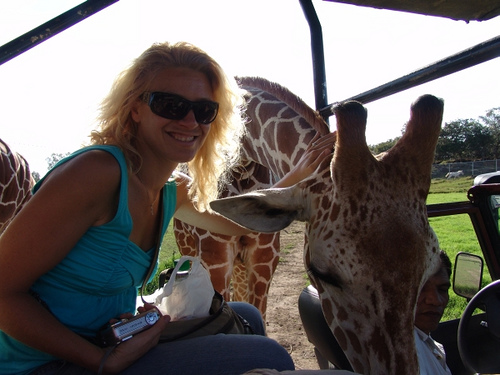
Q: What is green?
A: Grass.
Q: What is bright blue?
A: Woman's shirt.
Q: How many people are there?
A: One.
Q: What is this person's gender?
A: Female.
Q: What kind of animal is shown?
A: Giraffe.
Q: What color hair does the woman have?
A: Blond.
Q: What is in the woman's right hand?
A: A camera.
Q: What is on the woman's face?
A: Sunglasses.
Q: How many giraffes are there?
A: Two.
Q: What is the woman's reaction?
A: Smiling.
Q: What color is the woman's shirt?
A: Teal.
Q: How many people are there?
A: Two.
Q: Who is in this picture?
A: A woman.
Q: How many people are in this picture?
A: One.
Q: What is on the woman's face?
A: Sunglasses.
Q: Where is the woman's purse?
A: Lap.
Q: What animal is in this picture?
A: Giraffe.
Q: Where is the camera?
A: In the woman's hand.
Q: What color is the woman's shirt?
A: Blue.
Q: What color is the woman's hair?
A: Blonde.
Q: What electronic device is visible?
A: Camera.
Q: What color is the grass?
A: Green.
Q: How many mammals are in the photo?
A: Three.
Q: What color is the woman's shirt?
A: Blue.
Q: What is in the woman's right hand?
A: Camera.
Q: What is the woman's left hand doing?
A: Petting a giraffe.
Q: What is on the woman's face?
A: Sunglasses.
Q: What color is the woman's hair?
A: Blonde.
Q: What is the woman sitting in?
A: Car.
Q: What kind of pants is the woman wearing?
A: Blue jeans.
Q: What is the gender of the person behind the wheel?
A: Male.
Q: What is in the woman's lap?
A: Purse and plastic bag.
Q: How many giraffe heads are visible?
A: One.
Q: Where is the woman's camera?
A: On her lap.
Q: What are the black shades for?
A: To protect the woman's eyes from the sun.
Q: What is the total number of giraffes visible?
A: Two.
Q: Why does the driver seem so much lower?
A: The woman's seat is higher.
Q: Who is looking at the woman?
A: The photographer.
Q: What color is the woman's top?
A: Blue.